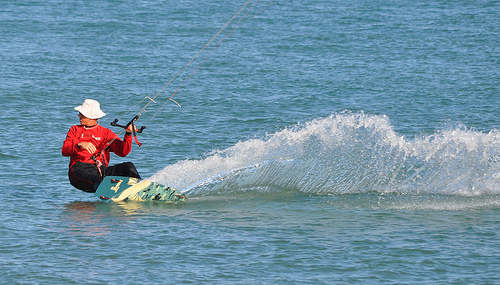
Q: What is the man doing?
A: Hang gliding.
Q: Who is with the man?
A: No one.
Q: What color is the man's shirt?
A: Red.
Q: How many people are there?
A: One.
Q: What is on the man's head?
A: Hat.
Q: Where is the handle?
A: Man's hand.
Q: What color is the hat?
A: White.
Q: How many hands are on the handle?
A: One.